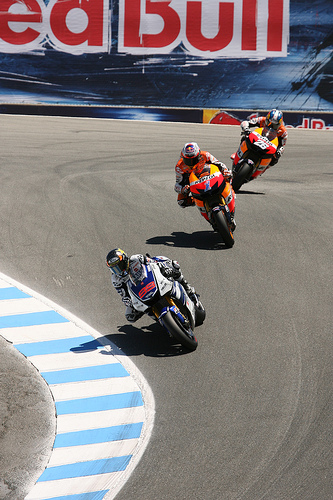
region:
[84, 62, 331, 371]
three people are racing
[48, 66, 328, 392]
they are racing motorcycles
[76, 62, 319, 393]
they are on a race track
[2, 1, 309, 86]
Red Bull logo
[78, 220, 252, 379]
his bike is blue and white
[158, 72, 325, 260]
their bikes are matching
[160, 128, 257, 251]
this bike is red and orange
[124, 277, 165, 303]
the number 99 is red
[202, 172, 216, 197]
the number one is shiny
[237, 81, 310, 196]
this bike is number 26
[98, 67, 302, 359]
three motorcycles in a race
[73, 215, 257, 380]
the lead motorcycle is blue and white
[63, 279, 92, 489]
blue and white stripes next to the road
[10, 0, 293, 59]
a slogan on a sign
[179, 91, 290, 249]
2 motorcycles have orange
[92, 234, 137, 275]
the man wears a helmet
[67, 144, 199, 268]
on the road marks are left from the tires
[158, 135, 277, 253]
the man tilts the bike to turn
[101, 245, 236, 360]
the bike is leaning to the right to turn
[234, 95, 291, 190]
this bike is leaning to the left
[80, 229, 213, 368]
Person on a motorcyclke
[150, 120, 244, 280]
Person on a motorcyclke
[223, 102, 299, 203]
Person on a motorcyclke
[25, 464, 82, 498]
White and blue strips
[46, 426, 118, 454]
White and blue strips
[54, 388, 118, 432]
White and blue strips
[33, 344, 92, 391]
White and blue strips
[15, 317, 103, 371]
White and blue strips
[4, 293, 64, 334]
White and blue strips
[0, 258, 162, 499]
White and blue strips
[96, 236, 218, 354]
person riding a bike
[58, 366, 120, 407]
blue and white on the side of the road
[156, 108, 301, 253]
people racing motor bikes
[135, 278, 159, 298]
number 98 on the bike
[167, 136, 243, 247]
person leaning to the left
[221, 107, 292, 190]
person leaning to the right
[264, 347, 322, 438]
tracks on the road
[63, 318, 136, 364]
shadow of the rider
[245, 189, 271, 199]
shadow of the tire on the ground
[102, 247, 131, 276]
helmet on the person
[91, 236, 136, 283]
racer is wearing a helmet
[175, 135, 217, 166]
racer is wearing a helmet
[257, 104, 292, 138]
racer is wearing a helmet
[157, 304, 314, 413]
the race track is paved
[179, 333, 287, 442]
the race track is paved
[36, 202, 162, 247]
the race track is paved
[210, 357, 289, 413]
the race track is paved